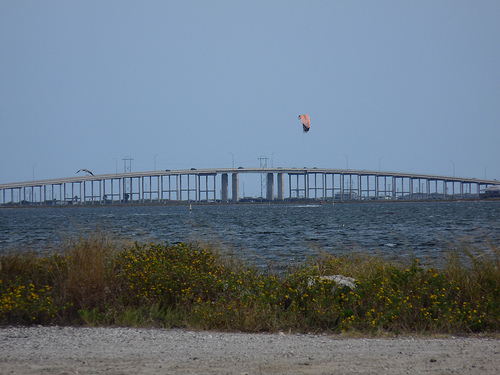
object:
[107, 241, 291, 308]
flowers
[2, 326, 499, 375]
sand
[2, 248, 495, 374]
ground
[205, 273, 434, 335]
weeds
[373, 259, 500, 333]
plant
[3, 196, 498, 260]
ocean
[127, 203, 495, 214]
ripple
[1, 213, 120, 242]
ripple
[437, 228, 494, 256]
ripple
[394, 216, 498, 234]
ripple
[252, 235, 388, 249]
ripple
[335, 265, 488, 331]
flowers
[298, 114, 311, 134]
kite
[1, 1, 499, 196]
sky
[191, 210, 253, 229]
ripples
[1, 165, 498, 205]
bridge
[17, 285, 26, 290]
flower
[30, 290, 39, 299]
flower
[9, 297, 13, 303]
flower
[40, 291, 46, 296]
flower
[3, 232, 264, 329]
plant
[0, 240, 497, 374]
area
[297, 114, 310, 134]
parasail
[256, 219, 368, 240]
ripple